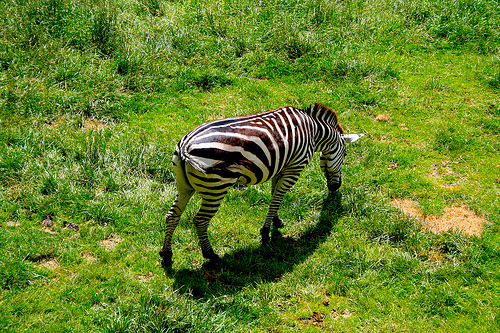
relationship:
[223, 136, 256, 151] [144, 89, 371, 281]
stripe on zebra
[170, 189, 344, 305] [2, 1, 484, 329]
shadow casted on ground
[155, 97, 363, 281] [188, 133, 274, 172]
zebra has stripe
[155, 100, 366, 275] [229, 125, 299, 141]
zebra has stripe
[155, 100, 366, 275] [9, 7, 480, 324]
zebra eating grass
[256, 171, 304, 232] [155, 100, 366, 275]
leg belonging to zebra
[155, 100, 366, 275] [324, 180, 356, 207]
zebra eating grass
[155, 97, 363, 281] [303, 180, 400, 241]
zebra eating grass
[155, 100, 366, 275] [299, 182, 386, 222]
zebra eating grass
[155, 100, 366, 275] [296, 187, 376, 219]
zebra eating grass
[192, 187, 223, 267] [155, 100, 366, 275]
leg of zebra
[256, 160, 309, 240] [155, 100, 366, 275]
leg of zebra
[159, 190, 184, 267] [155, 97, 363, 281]
leg of zebra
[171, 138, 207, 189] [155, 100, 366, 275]
tail of zebra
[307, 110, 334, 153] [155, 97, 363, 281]
neck of zebra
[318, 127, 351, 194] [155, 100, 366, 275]
head of zebra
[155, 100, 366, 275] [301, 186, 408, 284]
zebra eating grass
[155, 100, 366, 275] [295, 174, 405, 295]
zebra eating grass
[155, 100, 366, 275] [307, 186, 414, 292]
zebra eating grass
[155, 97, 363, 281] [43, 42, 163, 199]
zebra eating grass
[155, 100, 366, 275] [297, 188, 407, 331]
zebra eating grass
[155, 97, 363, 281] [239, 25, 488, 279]
zebra eats grass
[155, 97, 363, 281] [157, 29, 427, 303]
zebra eats grass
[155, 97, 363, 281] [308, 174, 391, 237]
zebra on grass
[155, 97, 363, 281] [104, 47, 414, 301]
zebra in grass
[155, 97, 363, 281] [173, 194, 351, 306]
zebra has shadow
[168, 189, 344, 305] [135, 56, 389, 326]
shadow on ground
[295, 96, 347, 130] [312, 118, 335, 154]
hair on neck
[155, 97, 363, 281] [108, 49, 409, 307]
zebra in field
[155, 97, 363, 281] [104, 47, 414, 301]
zebra on grass